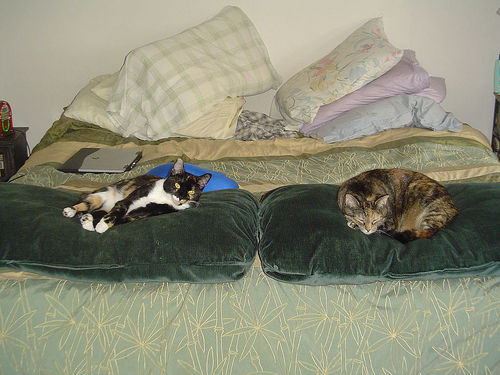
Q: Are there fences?
A: No, there are no fences.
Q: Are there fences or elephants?
A: No, there are no fences or elephants.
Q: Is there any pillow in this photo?
A: Yes, there is a pillow.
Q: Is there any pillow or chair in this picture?
A: Yes, there is a pillow.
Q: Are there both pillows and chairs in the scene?
A: No, there is a pillow but no chairs.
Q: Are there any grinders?
A: No, there are no grinders.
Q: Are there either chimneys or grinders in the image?
A: No, there are no grinders or chimneys.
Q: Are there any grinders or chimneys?
A: No, there are no grinders or chimneys.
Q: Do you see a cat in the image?
A: Yes, there is a cat.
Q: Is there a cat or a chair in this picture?
A: Yes, there is a cat.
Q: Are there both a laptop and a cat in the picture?
A: Yes, there are both a cat and a laptop.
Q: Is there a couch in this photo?
A: No, there are no couches.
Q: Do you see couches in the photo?
A: No, there are no couches.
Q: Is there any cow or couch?
A: No, there are no couches or cows.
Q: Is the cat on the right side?
A: Yes, the cat is on the right of the image.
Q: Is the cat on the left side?
A: No, the cat is on the right of the image.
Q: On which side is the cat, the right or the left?
A: The cat is on the right of the image.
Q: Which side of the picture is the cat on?
A: The cat is on the right of the image.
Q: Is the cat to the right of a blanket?
A: No, the cat is to the right of the pillow.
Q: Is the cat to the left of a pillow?
A: No, the cat is to the right of a pillow.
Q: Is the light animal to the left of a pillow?
A: No, the cat is to the right of a pillow.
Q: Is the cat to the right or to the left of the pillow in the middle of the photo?
A: The cat is to the right of the pillow.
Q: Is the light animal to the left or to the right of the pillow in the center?
A: The cat is to the right of the pillow.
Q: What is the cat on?
A: The cat is on the pillow.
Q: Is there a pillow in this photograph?
A: Yes, there is a pillow.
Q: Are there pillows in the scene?
A: Yes, there is a pillow.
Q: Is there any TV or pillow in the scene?
A: Yes, there is a pillow.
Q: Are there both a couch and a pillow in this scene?
A: No, there is a pillow but no couches.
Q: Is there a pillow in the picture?
A: Yes, there is a pillow.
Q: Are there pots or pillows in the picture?
A: Yes, there is a pillow.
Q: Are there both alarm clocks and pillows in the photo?
A: No, there is a pillow but no alarm clocks.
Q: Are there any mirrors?
A: No, there are no mirrors.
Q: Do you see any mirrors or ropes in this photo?
A: No, there are no mirrors or ropes.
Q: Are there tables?
A: Yes, there is a table.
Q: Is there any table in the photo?
A: Yes, there is a table.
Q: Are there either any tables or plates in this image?
A: Yes, there is a table.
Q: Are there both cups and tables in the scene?
A: No, there is a table but no cups.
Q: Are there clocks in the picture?
A: No, there are no clocks.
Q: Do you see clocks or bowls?
A: No, there are no clocks or bowls.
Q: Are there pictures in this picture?
A: No, there are no pictures.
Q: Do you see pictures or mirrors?
A: No, there are no pictures or mirrors.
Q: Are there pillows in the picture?
A: Yes, there is a pillow.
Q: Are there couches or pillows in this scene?
A: Yes, there is a pillow.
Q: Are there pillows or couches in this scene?
A: Yes, there is a pillow.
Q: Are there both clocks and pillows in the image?
A: No, there is a pillow but no clocks.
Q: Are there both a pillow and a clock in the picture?
A: No, there is a pillow but no clocks.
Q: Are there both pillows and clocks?
A: No, there is a pillow but no clocks.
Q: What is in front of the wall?
A: The pillow is in front of the wall.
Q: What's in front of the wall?
A: The pillow is in front of the wall.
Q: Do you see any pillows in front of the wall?
A: Yes, there is a pillow in front of the wall.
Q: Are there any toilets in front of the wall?
A: No, there is a pillow in front of the wall.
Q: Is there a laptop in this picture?
A: Yes, there is a laptop.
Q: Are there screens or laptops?
A: Yes, there is a laptop.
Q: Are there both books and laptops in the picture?
A: No, there is a laptop but no books.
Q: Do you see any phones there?
A: No, there are no phones.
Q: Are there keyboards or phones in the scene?
A: No, there are no phones or keyboards.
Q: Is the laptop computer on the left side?
A: Yes, the laptop computer is on the left of the image.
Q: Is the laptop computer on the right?
A: No, the laptop computer is on the left of the image.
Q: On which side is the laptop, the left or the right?
A: The laptop is on the left of the image.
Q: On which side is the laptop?
A: The laptop is on the left of the image.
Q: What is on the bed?
A: The laptop computer is on the bed.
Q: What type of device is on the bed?
A: The device is a laptop.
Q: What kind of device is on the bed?
A: The device is a laptop.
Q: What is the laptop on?
A: The laptop is on the bed.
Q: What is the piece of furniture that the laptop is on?
A: The piece of furniture is a bed.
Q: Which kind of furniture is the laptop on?
A: The laptop is on the bed.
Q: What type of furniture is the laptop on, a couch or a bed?
A: The laptop is on a bed.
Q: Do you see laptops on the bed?
A: Yes, there is a laptop on the bed.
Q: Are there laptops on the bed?
A: Yes, there is a laptop on the bed.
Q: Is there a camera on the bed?
A: No, there is a laptop on the bed.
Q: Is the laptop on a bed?
A: Yes, the laptop is on a bed.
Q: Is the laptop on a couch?
A: No, the laptop is on a bed.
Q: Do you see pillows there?
A: Yes, there is a pillow.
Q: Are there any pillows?
A: Yes, there is a pillow.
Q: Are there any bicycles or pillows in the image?
A: Yes, there is a pillow.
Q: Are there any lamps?
A: No, there are no lamps.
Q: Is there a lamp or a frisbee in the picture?
A: No, there are no lamps or frisbees.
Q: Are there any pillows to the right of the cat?
A: No, the pillow is to the left of the cat.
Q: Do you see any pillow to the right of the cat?
A: No, the pillow is to the left of the cat.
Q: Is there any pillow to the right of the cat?
A: No, the pillow is to the left of the cat.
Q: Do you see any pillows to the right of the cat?
A: No, the pillow is to the left of the cat.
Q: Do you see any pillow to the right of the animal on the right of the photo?
A: No, the pillow is to the left of the cat.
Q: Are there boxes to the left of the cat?
A: No, there is a pillow to the left of the cat.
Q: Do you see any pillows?
A: Yes, there is a pillow.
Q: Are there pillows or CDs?
A: Yes, there is a pillow.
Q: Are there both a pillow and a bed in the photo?
A: Yes, there are both a pillow and a bed.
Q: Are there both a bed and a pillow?
A: Yes, there are both a pillow and a bed.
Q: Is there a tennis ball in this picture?
A: No, there are no tennis balls.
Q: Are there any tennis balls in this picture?
A: No, there are no tennis balls.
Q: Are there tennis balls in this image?
A: No, there are no tennis balls.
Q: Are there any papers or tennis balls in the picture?
A: No, there are no tennis balls or papers.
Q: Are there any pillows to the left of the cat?
A: Yes, there is a pillow to the left of the cat.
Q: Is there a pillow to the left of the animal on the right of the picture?
A: Yes, there is a pillow to the left of the cat.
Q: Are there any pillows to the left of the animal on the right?
A: Yes, there is a pillow to the left of the cat.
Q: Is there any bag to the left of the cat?
A: No, there is a pillow to the left of the cat.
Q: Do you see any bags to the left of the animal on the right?
A: No, there is a pillow to the left of the cat.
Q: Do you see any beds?
A: Yes, there is a bed.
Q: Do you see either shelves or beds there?
A: Yes, there is a bed.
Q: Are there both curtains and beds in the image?
A: No, there is a bed but no curtains.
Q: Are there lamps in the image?
A: No, there are no lamps.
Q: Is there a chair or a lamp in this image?
A: No, there are no lamps or chairs.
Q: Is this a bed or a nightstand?
A: This is a bed.